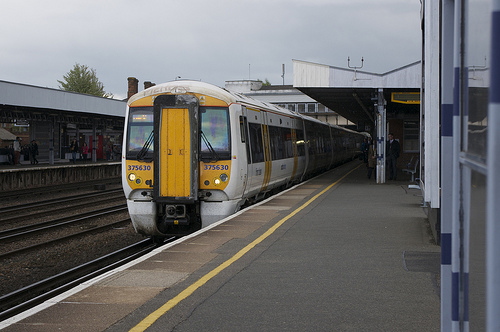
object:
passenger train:
[120, 79, 373, 246]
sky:
[1, 1, 424, 111]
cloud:
[102, 92, 125, 101]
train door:
[159, 107, 191, 196]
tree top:
[56, 61, 115, 99]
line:
[126, 163, 363, 332]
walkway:
[1, 160, 450, 332]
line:
[0, 169, 333, 330]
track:
[2, 184, 178, 316]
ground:
[0, 178, 196, 313]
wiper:
[199, 130, 221, 161]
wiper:
[136, 130, 156, 160]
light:
[214, 179, 221, 185]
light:
[128, 173, 135, 181]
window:
[199, 106, 232, 160]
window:
[128, 107, 157, 160]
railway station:
[0, 79, 442, 332]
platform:
[0, 155, 122, 193]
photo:
[1, 2, 499, 328]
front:
[125, 92, 232, 197]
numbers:
[204, 164, 229, 170]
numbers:
[128, 165, 151, 171]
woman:
[366, 139, 377, 180]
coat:
[368, 145, 377, 168]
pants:
[367, 167, 376, 182]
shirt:
[372, 144, 376, 155]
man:
[386, 133, 401, 181]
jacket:
[386, 139, 400, 160]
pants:
[386, 154, 398, 180]